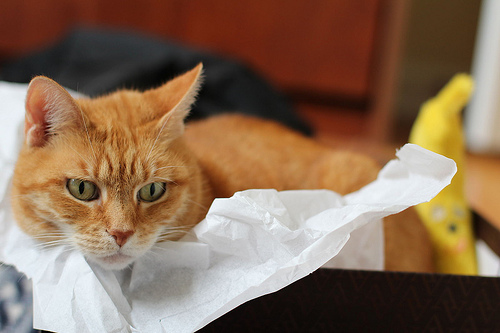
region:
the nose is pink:
[107, 229, 135, 251]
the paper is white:
[6, 129, 448, 328]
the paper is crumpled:
[50, 127, 437, 332]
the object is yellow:
[392, 72, 477, 273]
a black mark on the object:
[446, 219, 459, 234]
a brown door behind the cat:
[175, 0, 383, 121]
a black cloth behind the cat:
[20, 23, 324, 139]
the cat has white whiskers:
[24, 219, 207, 269]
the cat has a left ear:
[130, 179, 169, 202]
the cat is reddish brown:
[30, 76, 427, 281]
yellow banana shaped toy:
[411, 77, 480, 272]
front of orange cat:
[12, 64, 415, 266]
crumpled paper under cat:
[1, 85, 456, 331]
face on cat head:
[18, 60, 203, 268]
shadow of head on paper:
[129, 238, 203, 303]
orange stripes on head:
[89, 95, 165, 177]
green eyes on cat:
[66, 176, 171, 202]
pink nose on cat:
[107, 229, 137, 248]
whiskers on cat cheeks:
[38, 231, 103, 256]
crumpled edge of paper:
[208, 142, 458, 329]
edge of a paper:
[236, 263, 287, 314]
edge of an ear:
[169, 86, 193, 115]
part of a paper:
[308, 203, 346, 248]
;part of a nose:
[109, 221, 134, 253]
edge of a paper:
[318, 203, 370, 268]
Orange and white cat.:
[0, 64, 432, 270]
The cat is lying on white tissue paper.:
[1, 63, 455, 332]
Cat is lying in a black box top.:
[0, 62, 498, 329]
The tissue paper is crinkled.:
[0, 80, 455, 330]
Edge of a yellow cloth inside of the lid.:
[405, 71, 475, 271]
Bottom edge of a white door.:
[460, 45, 497, 150]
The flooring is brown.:
[302, 135, 497, 228]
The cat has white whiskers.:
[28, 218, 198, 261]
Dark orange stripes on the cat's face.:
[18, 142, 189, 227]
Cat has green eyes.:
[61, 175, 172, 202]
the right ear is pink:
[21, 73, 78, 142]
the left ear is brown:
[127, 60, 207, 138]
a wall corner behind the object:
[362, 0, 477, 152]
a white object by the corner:
[457, 0, 498, 173]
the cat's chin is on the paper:
[9, 67, 204, 267]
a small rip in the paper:
[376, 132, 407, 167]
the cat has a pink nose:
[100, 209, 138, 249]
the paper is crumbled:
[0, 138, 468, 324]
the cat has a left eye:
[140, 173, 169, 202]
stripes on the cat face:
[92, 147, 147, 179]